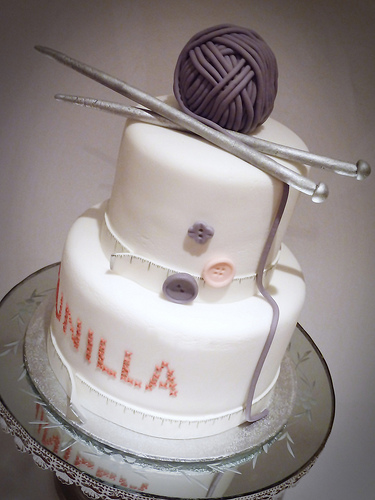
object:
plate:
[0, 256, 336, 498]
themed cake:
[46, 91, 313, 442]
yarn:
[199, 116, 239, 147]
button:
[184, 220, 215, 249]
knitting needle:
[53, 90, 370, 183]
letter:
[145, 358, 178, 399]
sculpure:
[0, 22, 373, 498]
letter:
[119, 350, 142, 388]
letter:
[96, 339, 115, 380]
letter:
[84, 326, 96, 364]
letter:
[61, 302, 82, 349]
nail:
[28, 41, 329, 204]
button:
[161, 273, 197, 305]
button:
[203, 256, 237, 289]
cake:
[42, 96, 311, 443]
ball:
[171, 19, 280, 134]